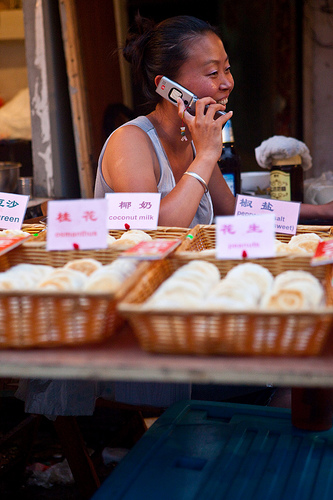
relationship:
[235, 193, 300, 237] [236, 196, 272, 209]
food label with letters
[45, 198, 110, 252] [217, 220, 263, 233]
food label with letters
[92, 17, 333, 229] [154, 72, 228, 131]
lady talking on cell phone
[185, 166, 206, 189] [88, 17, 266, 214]
bracelet worn by woman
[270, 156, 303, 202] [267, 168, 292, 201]
jar with label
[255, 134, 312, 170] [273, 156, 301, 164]
leather couch on top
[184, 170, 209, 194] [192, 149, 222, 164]
bracelet on wrist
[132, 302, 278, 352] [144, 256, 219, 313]
basket of pastries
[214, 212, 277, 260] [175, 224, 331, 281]
label attached to bascket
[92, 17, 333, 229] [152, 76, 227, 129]
lady talking on cell phone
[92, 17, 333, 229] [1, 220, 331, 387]
lady sitting at table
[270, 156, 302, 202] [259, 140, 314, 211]
jar with liquid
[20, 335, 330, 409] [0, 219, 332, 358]
table of desserts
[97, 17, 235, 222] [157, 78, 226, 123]
lady talking on cell phone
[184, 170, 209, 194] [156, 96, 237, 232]
bracelet on arm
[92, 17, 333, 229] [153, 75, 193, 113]
lady speaking on cellphone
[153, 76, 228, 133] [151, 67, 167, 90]
cell phone held to ear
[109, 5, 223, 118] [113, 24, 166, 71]
hair in bun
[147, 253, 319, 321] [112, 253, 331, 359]
food in a basket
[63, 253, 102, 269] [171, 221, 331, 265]
food in a basket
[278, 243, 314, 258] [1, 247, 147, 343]
food in a basket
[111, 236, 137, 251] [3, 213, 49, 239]
food in a basket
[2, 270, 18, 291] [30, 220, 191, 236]
food in a basket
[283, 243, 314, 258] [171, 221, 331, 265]
food in a basket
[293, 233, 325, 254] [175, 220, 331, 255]
food in a basket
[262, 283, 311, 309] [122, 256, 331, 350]
food in a basket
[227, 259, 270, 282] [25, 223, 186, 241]
food in a basket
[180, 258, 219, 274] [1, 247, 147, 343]
food in a basket